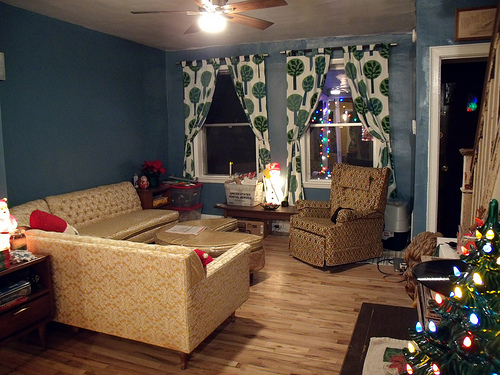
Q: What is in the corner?
A: Christmas tree.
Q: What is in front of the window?
A: Arm chair.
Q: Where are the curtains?
A: On the windows.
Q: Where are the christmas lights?
A: On the tree.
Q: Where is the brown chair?
A: In front of the window.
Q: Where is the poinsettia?
A: On the shelf in the corner.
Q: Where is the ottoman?
A: Near the couch.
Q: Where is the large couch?
A: Against the wall.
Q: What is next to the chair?
A: A brown table.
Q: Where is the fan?
A: On the ceiling.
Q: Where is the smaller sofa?
A: Near the larger sofa.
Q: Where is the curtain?
A: On the window.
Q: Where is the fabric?
A: On the window.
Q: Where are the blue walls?
A: In the living room.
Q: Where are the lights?
A: On the tree.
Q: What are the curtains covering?
A: The windows.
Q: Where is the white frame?
A: Around the door.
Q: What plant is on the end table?
A: A poinsettia.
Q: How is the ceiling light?
A: On.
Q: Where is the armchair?
A: By the window.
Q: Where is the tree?
A: In the living room.